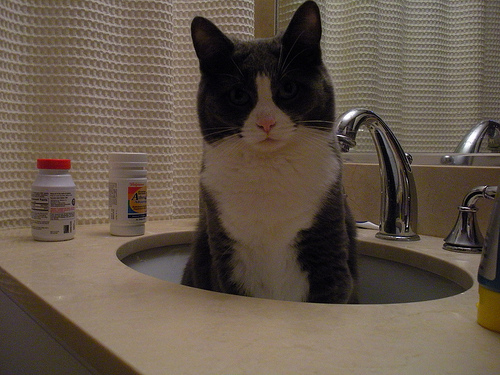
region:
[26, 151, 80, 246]
White medicine bottle on the counter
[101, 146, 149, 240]
A white medicine bottle on the sink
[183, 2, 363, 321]
A grey and white cat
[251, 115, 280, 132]
The pink nose of the cat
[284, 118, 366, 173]
The whiskers on the right side of the cat's nose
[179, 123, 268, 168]
The whiskers on the left side of the cat's nose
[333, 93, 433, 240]
The silver faucet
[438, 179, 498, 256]
The silver handle for the cold water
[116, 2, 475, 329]
A furry cat sitting in the bathroom sink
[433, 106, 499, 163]
The reflection of the silver faucet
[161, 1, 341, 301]
grey and white cat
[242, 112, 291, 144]
small pink cat's nose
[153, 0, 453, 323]
cat sitting in a bathroom sink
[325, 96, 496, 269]
silver faucet and handles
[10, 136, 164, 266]
two white medicine bottles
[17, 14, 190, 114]
white shower curtain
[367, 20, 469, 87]
reflection of shower curtain in mirror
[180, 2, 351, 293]
cat looking directly at camera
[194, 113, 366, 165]
cat's white whiskars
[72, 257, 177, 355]
light tan counter top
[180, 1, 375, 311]
a cat in a sink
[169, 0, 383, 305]
a grey and white cat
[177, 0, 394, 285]
a grey and white cat in the basin of a sink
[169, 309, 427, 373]
a marble counter top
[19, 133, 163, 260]
bottles of vitamins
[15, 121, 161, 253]
bottles of supplements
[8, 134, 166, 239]
pills in white bottles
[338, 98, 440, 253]
silver colored faucet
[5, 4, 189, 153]
a white shower curtain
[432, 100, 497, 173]
reflection of the faucet in the mirror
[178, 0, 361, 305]
cat is black and white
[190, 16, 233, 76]
little furry right ear of cat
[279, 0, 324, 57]
little furry left ear of cat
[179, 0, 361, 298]
black and white cat on handwash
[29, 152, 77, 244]
red and white plastic pot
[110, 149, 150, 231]
white plastic pot on handwash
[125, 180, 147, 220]
little orange blue and yellow label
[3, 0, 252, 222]
plaid beige curtains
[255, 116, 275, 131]
little pinky nose of black and white cat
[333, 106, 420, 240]
gray metal tap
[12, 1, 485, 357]
black and white cat in bathroom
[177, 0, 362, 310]
cat sitting in sink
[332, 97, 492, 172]
silver faucet reflected in mirror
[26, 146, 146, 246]
pill bottles on counter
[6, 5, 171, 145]
waffle texture of white curtains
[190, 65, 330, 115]
black patches over eyes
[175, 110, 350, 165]
white whiskers around pink nose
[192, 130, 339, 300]
long white area across chest and underside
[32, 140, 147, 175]
caps on tops of bottles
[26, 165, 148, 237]
labels around cylindrical surface